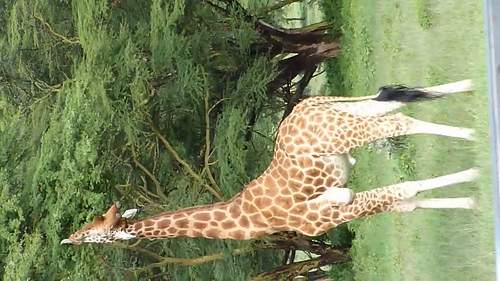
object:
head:
[60, 201, 138, 245]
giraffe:
[58, 79, 479, 245]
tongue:
[59, 238, 72, 245]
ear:
[113, 228, 136, 240]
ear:
[121, 208, 138, 220]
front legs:
[355, 167, 477, 221]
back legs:
[355, 79, 478, 141]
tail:
[308, 83, 447, 104]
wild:
[0, 3, 498, 280]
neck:
[131, 196, 252, 241]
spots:
[123, 94, 413, 242]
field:
[291, 0, 495, 281]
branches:
[0, 0, 342, 280]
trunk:
[253, 15, 337, 116]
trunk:
[97, 231, 342, 281]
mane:
[127, 189, 244, 224]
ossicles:
[92, 213, 107, 223]